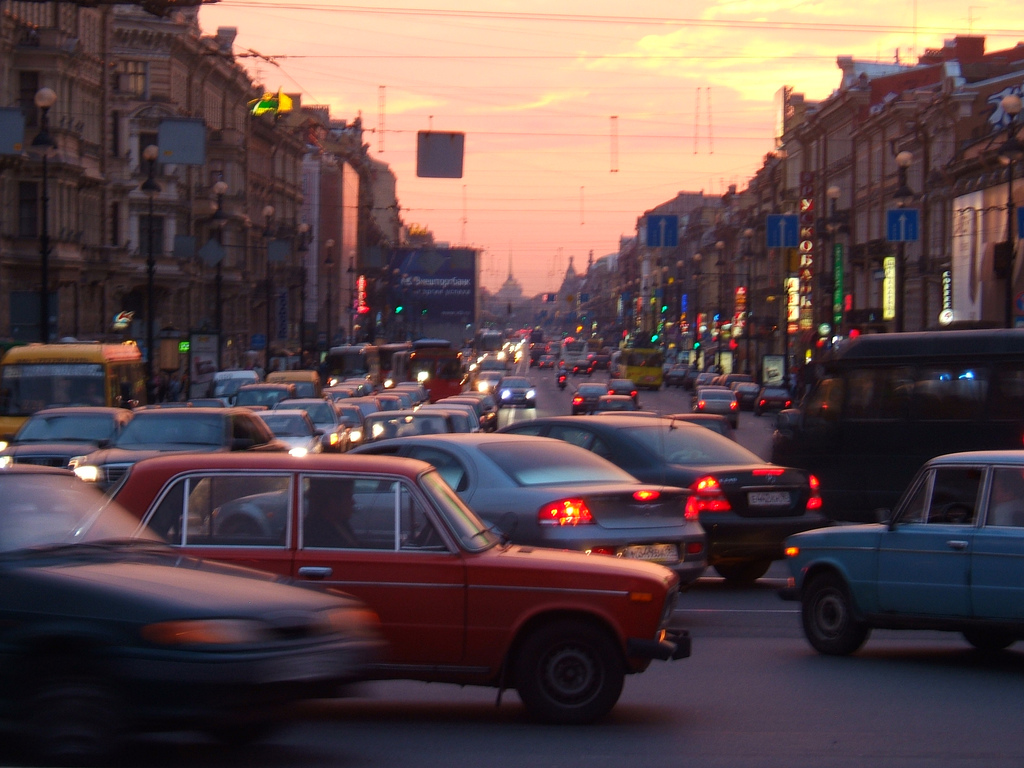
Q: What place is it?
A: It is a road.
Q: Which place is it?
A: It is a road.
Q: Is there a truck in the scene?
A: Yes, there is a truck.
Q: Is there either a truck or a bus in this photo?
A: Yes, there is a truck.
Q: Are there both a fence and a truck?
A: No, there is a truck but no fences.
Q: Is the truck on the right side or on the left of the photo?
A: The truck is on the left of the image.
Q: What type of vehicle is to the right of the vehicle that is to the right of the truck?
A: The vehicle is a car.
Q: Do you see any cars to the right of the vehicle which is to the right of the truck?
A: Yes, there is a car to the right of the vehicle.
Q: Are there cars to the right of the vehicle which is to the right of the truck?
A: Yes, there is a car to the right of the vehicle.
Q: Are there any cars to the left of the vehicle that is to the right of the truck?
A: No, the car is to the right of the vehicle.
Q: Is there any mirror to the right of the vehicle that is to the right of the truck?
A: No, there is a car to the right of the vehicle.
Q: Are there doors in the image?
A: Yes, there are doors.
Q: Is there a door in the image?
A: Yes, there are doors.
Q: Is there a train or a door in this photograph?
A: Yes, there are doors.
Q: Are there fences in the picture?
A: No, there are no fences.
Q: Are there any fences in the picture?
A: No, there are no fences.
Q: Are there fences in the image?
A: No, there are no fences.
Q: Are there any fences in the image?
A: No, there are no fences.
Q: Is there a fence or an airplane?
A: No, there are no fences or airplanes.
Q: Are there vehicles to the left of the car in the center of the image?
A: Yes, there is a vehicle to the left of the car.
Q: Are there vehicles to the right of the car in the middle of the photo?
A: No, the vehicle is to the left of the car.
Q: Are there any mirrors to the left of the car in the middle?
A: No, there is a vehicle to the left of the car.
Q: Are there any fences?
A: No, there are no fences.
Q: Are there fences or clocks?
A: No, there are no fences or clocks.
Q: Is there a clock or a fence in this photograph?
A: No, there are no fences or clocks.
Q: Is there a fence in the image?
A: No, there are no fences.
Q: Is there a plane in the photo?
A: No, there are no airplanes.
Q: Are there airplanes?
A: No, there are no airplanes.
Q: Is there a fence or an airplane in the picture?
A: No, there are no airplanes or fences.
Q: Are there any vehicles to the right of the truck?
A: Yes, there is a vehicle to the right of the truck.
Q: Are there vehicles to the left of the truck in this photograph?
A: No, the vehicle is to the right of the truck.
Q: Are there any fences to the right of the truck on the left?
A: No, there is a vehicle to the right of the truck.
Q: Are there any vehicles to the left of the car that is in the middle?
A: Yes, there is a vehicle to the left of the car.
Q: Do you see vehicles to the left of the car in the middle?
A: Yes, there is a vehicle to the left of the car.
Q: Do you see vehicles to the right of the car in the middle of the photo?
A: No, the vehicle is to the left of the car.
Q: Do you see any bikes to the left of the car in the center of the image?
A: No, there is a vehicle to the left of the car.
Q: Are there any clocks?
A: No, there are no clocks.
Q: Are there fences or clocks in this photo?
A: No, there are no clocks or fences.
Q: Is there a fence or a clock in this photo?
A: No, there are no clocks or fences.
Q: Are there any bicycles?
A: No, there are no bicycles.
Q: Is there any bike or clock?
A: No, there are no bikes or clocks.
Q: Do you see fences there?
A: No, there are no fences.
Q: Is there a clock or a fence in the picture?
A: No, there are no fences or clocks.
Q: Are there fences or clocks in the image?
A: No, there are no fences or clocks.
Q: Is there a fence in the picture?
A: No, there are no fences.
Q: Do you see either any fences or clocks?
A: No, there are no fences or clocks.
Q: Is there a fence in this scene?
A: No, there are no fences.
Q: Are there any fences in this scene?
A: No, there are no fences.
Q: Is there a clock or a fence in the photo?
A: No, there are no fences or clocks.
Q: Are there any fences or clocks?
A: No, there are no fences or clocks.